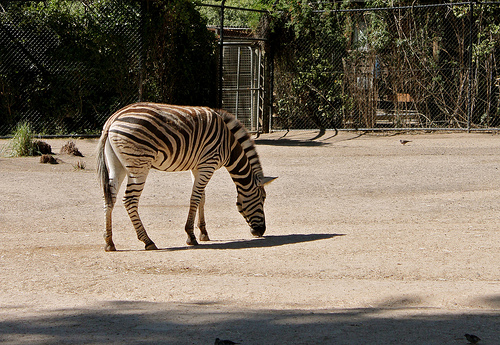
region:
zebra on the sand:
[88, 98, 290, 282]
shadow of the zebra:
[193, 227, 364, 256]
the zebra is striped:
[75, 93, 283, 255]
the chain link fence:
[280, 1, 494, 136]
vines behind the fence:
[363, 14, 495, 134]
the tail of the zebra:
[90, 135, 127, 207]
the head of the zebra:
[237, 175, 275, 237]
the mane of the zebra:
[215, 112, 271, 173]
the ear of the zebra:
[257, 170, 282, 189]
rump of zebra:
[108, 112, 150, 165]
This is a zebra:
[91, 88, 293, 255]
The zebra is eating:
[53, 90, 328, 255]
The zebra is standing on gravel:
[0, 154, 479, 289]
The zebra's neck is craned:
[212, 116, 288, 250]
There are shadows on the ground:
[46, 285, 454, 337]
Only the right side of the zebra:
[68, 94, 313, 246]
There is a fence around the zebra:
[14, 8, 482, 135]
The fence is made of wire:
[6, 8, 485, 130]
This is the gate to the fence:
[222, 45, 268, 133]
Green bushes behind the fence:
[5, 9, 215, 129]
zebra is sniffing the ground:
[52, 79, 309, 291]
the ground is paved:
[291, 136, 403, 250]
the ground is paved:
[331, 174, 465, 306]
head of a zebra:
[228, 178, 279, 240]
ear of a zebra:
[252, 169, 277, 193]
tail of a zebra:
[87, 128, 121, 214]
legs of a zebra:
[94, 176, 221, 258]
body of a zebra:
[102, 90, 225, 181]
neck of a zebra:
[225, 148, 264, 186]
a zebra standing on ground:
[74, 99, 286, 259]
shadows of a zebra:
[209, 227, 351, 265]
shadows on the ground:
[265, 115, 332, 154]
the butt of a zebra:
[102, 110, 145, 172]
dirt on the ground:
[30, 134, 100, 191]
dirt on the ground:
[35, 151, 65, 173]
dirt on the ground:
[30, 145, 70, 179]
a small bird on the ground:
[387, 134, 410, 150]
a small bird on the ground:
[391, 133, 416, 155]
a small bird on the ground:
[396, 125, 415, 150]